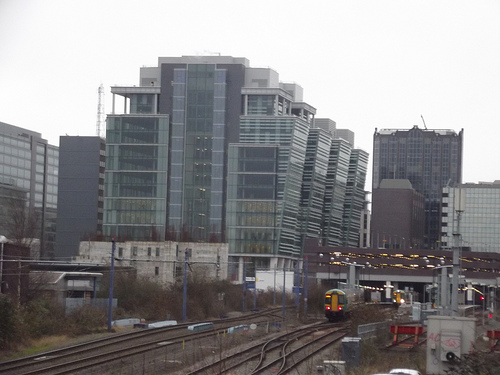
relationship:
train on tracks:
[327, 281, 373, 322] [180, 307, 411, 374]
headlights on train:
[337, 306, 342, 312] [327, 281, 373, 322]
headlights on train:
[325, 305, 329, 311] [327, 281, 373, 322]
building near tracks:
[103, 55, 370, 295] [180, 307, 411, 374]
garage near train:
[302, 242, 500, 283] [327, 281, 373, 322]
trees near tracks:
[2, 193, 46, 323] [180, 307, 411, 374]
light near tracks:
[478, 294, 485, 300] [180, 307, 411, 374]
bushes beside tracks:
[2, 290, 108, 356] [180, 307, 411, 374]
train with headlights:
[327, 281, 373, 322] [337, 306, 342, 312]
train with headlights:
[327, 281, 373, 322] [325, 305, 329, 311]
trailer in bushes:
[62, 298, 117, 323] [2, 290, 108, 356]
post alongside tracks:
[104, 239, 117, 334] [180, 307, 411, 374]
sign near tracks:
[390, 323, 424, 336] [180, 307, 411, 374]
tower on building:
[132, 56, 286, 94] [103, 55, 370, 295]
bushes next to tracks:
[2, 290, 108, 356] [180, 307, 411, 374]